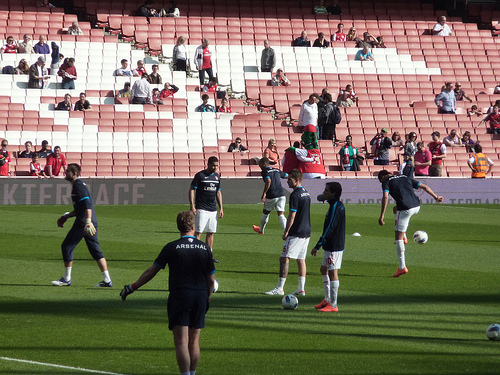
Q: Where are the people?
A: On the field.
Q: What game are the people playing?
A: Soccer.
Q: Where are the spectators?
A: In the stands.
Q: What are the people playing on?
A: Astroturf.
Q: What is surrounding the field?
A: The fence.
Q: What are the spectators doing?
A: Watching the players.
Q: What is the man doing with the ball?
A: Kicking it.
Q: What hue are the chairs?
A: White and red.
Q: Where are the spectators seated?
A: In the grandstands of a sports stadium.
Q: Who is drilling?
A: A soccer player.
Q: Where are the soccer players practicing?
A: On a field.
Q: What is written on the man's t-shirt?
A: Arsenal.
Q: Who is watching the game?
A: The spectators.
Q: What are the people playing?
A: Soccer.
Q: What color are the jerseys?
A: Blue.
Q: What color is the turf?
A: Green.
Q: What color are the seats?
A: Red and white.